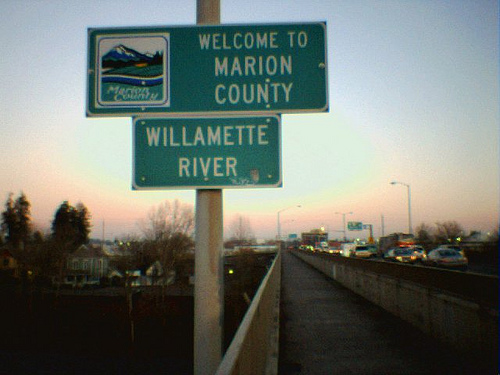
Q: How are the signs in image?
A: Green.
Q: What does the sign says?
A: WILLAMETTE RIVER.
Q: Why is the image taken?
A: Remembrance.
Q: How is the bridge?
A: Very long.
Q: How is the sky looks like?
A: Hazy.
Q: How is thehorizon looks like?
A: Pink.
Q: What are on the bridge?
A: Cars.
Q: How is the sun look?
A: Rising.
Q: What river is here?
A: Willamette.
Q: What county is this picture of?
A: Marion.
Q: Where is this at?
A: A bridge.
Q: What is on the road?
A: Cars.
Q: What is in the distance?
A: Homes.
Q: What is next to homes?
A: Trees.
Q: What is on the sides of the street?
A: Lamp posts.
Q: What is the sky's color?
A: Blue.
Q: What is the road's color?
A: Gray.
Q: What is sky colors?
A: Blue and red.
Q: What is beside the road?
A: Sidewalk.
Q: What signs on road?
A: Road signs.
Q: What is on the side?
A: Trees.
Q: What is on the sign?
A: River name.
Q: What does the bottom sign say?
A: Willamette river.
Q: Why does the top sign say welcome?
A: Reached county line.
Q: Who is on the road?
A: Drivers.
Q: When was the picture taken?
A: Sunrise.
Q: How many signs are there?
A: Two.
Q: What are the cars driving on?
A: Bridge.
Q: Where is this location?
A: Marion county.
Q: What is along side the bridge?
A: Walk way.